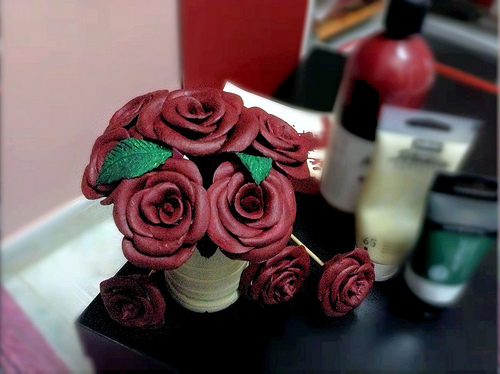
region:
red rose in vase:
[245, 110, 321, 189]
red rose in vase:
[202, 156, 301, 282]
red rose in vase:
[155, 90, 251, 150]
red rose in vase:
[81, 131, 150, 198]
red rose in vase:
[111, 176, 200, 273]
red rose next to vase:
[305, 233, 378, 325]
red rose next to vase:
[252, 235, 320, 309]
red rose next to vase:
[98, 251, 172, 328]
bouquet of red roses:
[52, 60, 321, 338]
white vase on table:
[164, 242, 254, 320]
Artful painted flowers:
[81, 78, 375, 341]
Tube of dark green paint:
[401, 165, 498, 311]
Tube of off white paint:
[348, 98, 483, 283]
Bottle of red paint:
[318, 0, 435, 227]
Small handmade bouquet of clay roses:
[82, 78, 319, 334]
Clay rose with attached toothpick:
[292, 219, 377, 324]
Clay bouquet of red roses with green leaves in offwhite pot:
[82, 82, 313, 331]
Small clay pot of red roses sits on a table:
[68, 4, 499, 369]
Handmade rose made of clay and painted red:
[208, 148, 301, 268]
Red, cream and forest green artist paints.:
[318, 7, 499, 301]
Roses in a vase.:
[88, 72, 296, 321]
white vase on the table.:
[151, 233, 248, 317]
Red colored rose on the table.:
[307, 243, 370, 318]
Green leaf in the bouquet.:
[94, 133, 171, 188]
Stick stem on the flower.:
[287, 233, 330, 275]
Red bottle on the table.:
[309, 1, 436, 251]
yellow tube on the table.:
[350, 104, 479, 303]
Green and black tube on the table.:
[402, 165, 494, 312]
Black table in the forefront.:
[75, 42, 495, 372]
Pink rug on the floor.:
[1, 286, 68, 371]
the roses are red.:
[74, 77, 374, 322]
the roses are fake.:
[68, 82, 380, 344]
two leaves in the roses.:
[84, 127, 276, 194]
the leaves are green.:
[87, 127, 282, 196]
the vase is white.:
[161, 237, 248, 319]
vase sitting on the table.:
[161, 236, 255, 324]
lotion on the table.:
[347, 93, 488, 308]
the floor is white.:
[13, 192, 124, 367]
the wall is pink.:
[2, 0, 172, 228]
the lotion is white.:
[340, 117, 477, 272]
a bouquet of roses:
[63, 68, 372, 340]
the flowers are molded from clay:
[72, 78, 392, 345]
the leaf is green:
[89, 132, 191, 189]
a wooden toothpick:
[282, 218, 329, 273]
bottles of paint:
[320, 15, 497, 324]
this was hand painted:
[52, 60, 389, 345]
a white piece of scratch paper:
[218, 70, 365, 175]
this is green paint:
[417, 169, 497, 323]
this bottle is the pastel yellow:
[361, 85, 449, 299]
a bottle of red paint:
[308, 0, 438, 230]